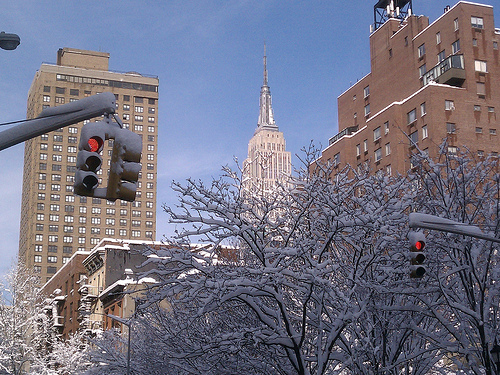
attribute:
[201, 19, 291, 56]
sky — blue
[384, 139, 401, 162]
window — glass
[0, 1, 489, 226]
sky — blue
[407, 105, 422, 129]
window — glass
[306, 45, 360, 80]
sky — blue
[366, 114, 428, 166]
window — glass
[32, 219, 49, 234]
window — glass